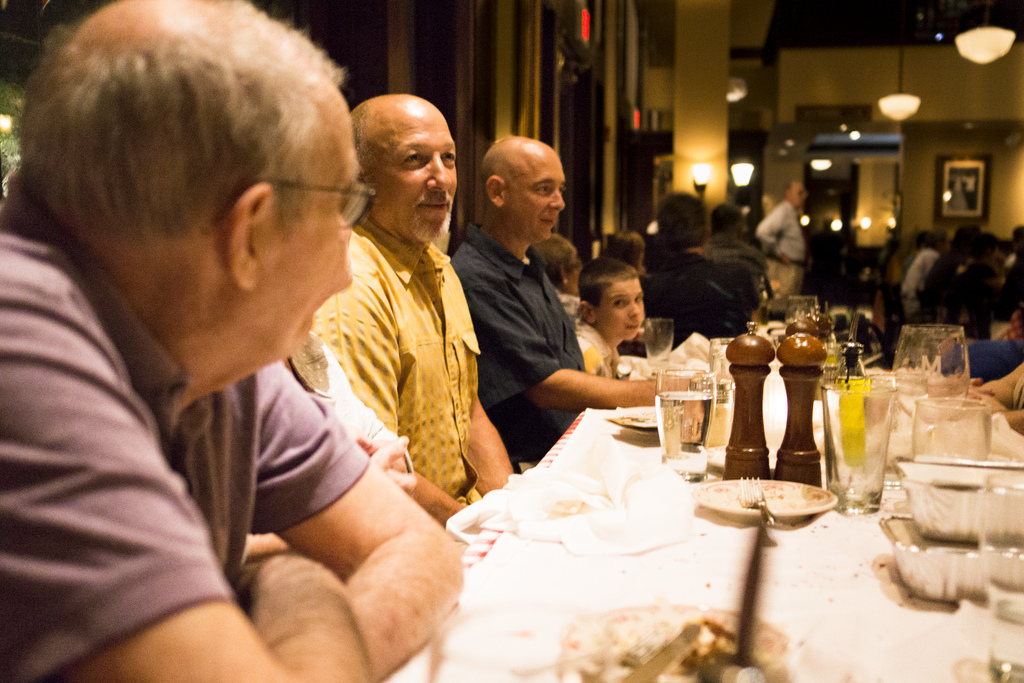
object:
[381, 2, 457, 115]
wall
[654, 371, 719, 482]
glass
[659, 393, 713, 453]
water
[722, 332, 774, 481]
shaker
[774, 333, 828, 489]
shaker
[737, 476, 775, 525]
fork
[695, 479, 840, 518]
plate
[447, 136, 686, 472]
man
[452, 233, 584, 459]
shirt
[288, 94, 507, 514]
man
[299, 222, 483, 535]
shirt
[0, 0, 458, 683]
man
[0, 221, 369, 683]
shirt